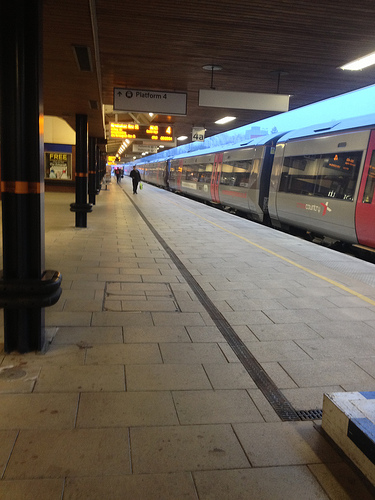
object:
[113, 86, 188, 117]
sign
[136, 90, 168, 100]
platform 4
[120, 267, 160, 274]
bricks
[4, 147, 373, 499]
sidewalk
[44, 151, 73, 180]
poster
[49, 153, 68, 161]
free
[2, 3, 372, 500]
subway station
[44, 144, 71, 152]
blue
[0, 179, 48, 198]
ring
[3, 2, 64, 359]
pole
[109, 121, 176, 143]
sign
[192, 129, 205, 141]
4a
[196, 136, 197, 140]
black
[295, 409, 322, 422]
drain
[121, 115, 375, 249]
subway train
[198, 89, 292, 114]
sign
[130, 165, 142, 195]
person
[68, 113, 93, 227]
pole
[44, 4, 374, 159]
ceiling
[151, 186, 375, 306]
yellow line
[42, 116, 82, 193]
wall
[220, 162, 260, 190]
windows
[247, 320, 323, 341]
cement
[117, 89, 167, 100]
writting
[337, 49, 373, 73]
light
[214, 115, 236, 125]
light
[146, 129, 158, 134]
writting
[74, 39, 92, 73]
vent